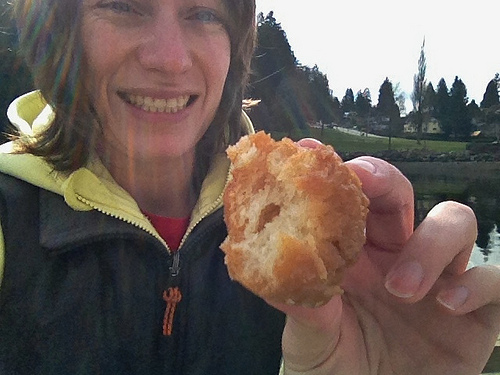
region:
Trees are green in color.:
[363, 89, 461, 186]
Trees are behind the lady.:
[333, 86, 493, 175]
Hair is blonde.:
[34, 13, 77, 80]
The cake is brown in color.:
[237, 136, 384, 299]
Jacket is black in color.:
[26, 265, 129, 356]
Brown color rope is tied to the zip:
[160, 288, 188, 333]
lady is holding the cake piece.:
[231, 136, 406, 319]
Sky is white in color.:
[298, 8, 409, 56]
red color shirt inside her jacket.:
[143, 207, 194, 259]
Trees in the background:
[255, 8, 498, 145]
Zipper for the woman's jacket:
[162, 251, 182, 337]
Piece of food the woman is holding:
[217, 131, 369, 311]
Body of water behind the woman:
[344, 153, 499, 270]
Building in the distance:
[402, 108, 444, 133]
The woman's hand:
[260, 135, 497, 374]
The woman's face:
[68, 1, 232, 167]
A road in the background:
[327, 124, 399, 139]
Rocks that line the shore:
[329, 146, 499, 165]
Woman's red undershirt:
[136, 210, 193, 252]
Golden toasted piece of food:
[192, 124, 403, 327]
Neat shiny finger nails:
[374, 230, 490, 341]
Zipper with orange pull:
[125, 235, 220, 360]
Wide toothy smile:
[95, 78, 221, 146]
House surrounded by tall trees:
[289, 21, 493, 154]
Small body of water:
[319, 109, 496, 262]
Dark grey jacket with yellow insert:
[9, 77, 325, 292]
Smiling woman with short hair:
[15, 0, 265, 191]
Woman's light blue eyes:
[65, 1, 252, 37]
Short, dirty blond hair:
[6, 5, 127, 187]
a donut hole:
[205, 128, 368, 320]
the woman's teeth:
[116, 87, 201, 120]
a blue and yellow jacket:
[7, 110, 285, 372]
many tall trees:
[338, 73, 489, 119]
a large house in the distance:
[401, 107, 462, 134]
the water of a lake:
[405, 161, 497, 253]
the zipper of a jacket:
[153, 250, 193, 373]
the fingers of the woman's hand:
[340, 173, 496, 316]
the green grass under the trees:
[302, 120, 472, 156]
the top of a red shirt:
[137, 205, 195, 256]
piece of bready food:
[217, 131, 369, 311]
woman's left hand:
[277, 132, 499, 373]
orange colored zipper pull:
[161, 284, 185, 341]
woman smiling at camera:
[3, 1, 310, 373]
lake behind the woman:
[309, 151, 499, 273]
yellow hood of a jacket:
[0, 88, 259, 248]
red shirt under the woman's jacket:
[140, 207, 195, 256]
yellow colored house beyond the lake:
[400, 107, 467, 137]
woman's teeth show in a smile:
[121, 91, 197, 118]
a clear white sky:
[245, 0, 498, 122]